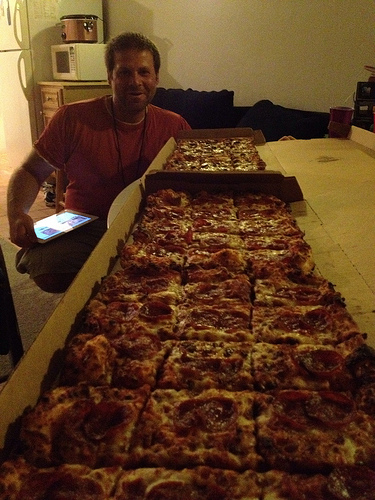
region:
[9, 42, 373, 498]
plenty of yummy looking pizza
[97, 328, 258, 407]
these have pepperoni on them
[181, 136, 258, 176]
this pizza appears to have different toppings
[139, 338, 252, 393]
lots of cheese on the pizza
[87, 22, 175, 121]
the man looks happy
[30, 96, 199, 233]
the man is wearing a red shirt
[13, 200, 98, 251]
the man has a "tablet" on his lap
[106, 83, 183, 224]
the man has a lanyard around his neck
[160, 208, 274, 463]
the pizza looks so good!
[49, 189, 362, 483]
all the pizzas are rectangular shaped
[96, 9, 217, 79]
Man has brown hair.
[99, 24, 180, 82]
Man has short hair.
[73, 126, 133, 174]
Man wearing red shirt.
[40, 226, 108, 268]
Man wearing khaki shorts.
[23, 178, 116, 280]
Man holding ipad.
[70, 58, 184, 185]
Man sitting at table near pizza.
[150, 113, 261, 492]
Pizza in boxes on table.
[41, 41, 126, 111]
White microwave on stand near wall.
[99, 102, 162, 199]
Black strap around man's neck.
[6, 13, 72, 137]
White refrigerator behind man.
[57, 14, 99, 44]
SILVER CROCK POT ON TOP OF A MICROWAVE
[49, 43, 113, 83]
WHITE MICROWAVE IN THE BACKGROUND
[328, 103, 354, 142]
PLASTIC RED SOLO CUP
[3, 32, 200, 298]
MAN HOLDING A TABLET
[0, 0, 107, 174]
WHITE REFRIGERATOR IN THE BACKGROUND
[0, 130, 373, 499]
PIZZA WITH PEPPERONI TOPPING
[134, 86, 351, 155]
BLUE COACH AGAINST A WALL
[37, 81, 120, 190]
WOODEN KITCHEN CABINETS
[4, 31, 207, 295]
MAN WEARING A RED SHIRT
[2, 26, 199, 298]
MAN WITH A LANYARD AROUND HIS NECK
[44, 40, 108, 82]
a white microwave oven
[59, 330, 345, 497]
pizza cut into squares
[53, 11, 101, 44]
a gold colored crock pot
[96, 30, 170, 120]
man with short hair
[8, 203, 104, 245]
a tablet device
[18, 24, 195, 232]
man wearing a red shirt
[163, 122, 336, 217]
pizza in a cardboard box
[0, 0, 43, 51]
white freezer handle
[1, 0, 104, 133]
a white refrigerator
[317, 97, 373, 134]
a red plastic cup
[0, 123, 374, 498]
cardboard boxes filled with pizza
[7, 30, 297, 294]
a man sitting next to the pizza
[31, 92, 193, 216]
orange shirt on the man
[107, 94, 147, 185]
black cord around man's neck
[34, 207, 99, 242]
tablet in man's hand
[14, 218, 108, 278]
shorts on man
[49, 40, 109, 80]
white microwave behind man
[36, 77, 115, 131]
wooden cabinet under microwave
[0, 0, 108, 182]
white refrigerator next to microwave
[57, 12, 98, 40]
crock pot on top of microwave